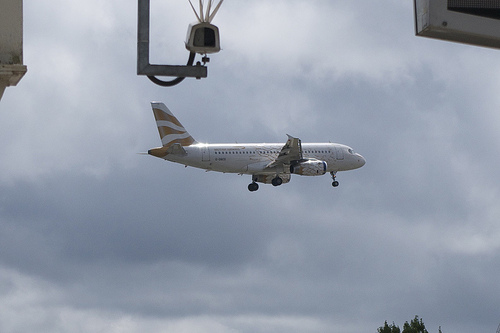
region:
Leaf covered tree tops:
[370, 313, 451, 331]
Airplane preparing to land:
[128, 100, 378, 200]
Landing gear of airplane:
[248, 171, 341, 192]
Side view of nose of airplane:
[348, 151, 368, 170]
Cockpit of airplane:
[342, 142, 357, 158]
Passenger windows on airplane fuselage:
[209, 146, 335, 156]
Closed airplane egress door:
[332, 144, 347, 162]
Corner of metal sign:
[395, 1, 497, 53]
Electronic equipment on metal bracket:
[128, 1, 229, 87]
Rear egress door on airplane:
[198, 143, 213, 163]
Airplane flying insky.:
[165, 112, 372, 209]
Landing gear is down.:
[236, 170, 358, 203]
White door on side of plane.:
[329, 143, 352, 178]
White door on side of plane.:
[198, 142, 223, 170]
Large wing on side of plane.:
[266, 132, 325, 183]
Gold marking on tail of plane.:
[150, 107, 195, 123]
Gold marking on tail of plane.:
[153, 122, 195, 137]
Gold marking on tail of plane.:
[154, 137, 196, 170]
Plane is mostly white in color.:
[128, 84, 380, 234]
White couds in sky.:
[33, 83, 122, 180]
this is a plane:
[135, 95, 390, 185]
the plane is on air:
[145, 101, 387, 182]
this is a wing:
[278, 131, 305, 158]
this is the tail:
[145, 95, 194, 143]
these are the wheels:
[250, 180, 262, 188]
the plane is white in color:
[220, 146, 245, 163]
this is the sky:
[99, 199, 283, 294]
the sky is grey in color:
[118, 203, 273, 296]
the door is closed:
[333, 144, 345, 156]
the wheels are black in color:
[245, 180, 261, 192]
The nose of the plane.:
[357, 156, 367, 166]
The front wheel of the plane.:
[327, 172, 339, 190]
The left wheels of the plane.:
[247, 180, 261, 190]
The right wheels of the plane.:
[273, 176, 283, 184]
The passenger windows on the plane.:
[212, 147, 332, 156]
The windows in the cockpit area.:
[346, 147, 357, 154]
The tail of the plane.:
[151, 104, 194, 141]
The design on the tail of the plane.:
[156, 112, 191, 144]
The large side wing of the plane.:
[274, 133, 305, 168]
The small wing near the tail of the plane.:
[168, 139, 193, 159]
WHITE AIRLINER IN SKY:
[143, 100, 395, 226]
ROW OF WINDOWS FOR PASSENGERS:
[202, 144, 333, 160]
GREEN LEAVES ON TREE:
[352, 304, 462, 332]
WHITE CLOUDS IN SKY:
[152, 236, 324, 313]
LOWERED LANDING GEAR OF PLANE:
[239, 187, 273, 192]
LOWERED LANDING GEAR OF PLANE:
[274, 180, 287, 191]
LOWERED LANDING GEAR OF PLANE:
[324, 171, 350, 199]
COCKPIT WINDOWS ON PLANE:
[341, 132, 363, 169]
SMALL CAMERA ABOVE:
[169, 14, 226, 69]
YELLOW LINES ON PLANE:
[138, 111, 201, 148]